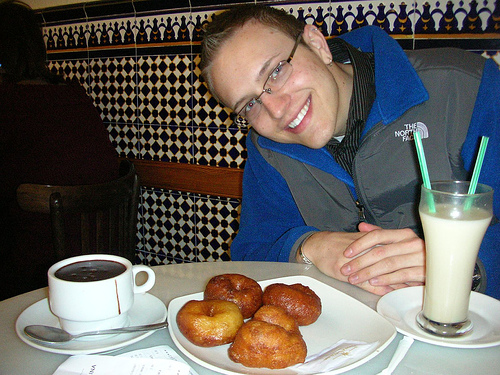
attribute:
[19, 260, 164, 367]
cup — white 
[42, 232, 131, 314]
saucer — white 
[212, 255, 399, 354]
plate — white , square 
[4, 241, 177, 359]
saucer — white , round 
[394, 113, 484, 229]
straws — green 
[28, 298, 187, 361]
teaspoon — silver 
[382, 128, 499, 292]
straws — two and green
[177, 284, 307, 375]
donuts — four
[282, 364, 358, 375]
plate — white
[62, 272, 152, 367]
mug — white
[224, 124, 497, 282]
chair —  brown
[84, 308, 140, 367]
plate — small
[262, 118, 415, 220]
jacket — blue and gray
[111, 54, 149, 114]
tiles — black and white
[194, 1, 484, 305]
man — smiling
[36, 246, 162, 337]
mug — coffee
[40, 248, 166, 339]
mug — coffee, white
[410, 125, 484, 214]
straws — green